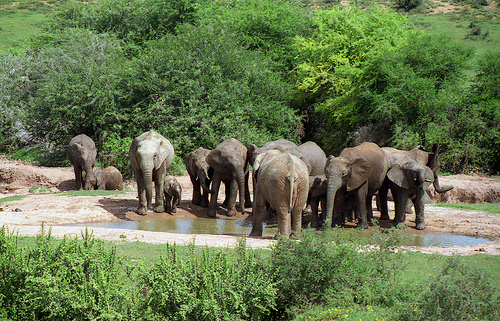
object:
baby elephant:
[162, 174, 182, 214]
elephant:
[66, 134, 97, 192]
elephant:
[185, 146, 216, 208]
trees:
[0, 32, 126, 165]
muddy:
[116, 201, 454, 235]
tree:
[292, 5, 420, 125]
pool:
[49, 214, 498, 249]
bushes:
[408, 254, 499, 319]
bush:
[0, 224, 79, 319]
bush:
[22, 226, 150, 319]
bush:
[139, 234, 198, 319]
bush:
[206, 233, 279, 319]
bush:
[266, 222, 356, 319]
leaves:
[360, 43, 372, 51]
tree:
[335, 36, 479, 150]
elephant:
[246, 148, 312, 243]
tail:
[286, 174, 298, 209]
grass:
[0, 235, 499, 294]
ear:
[343, 150, 374, 192]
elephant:
[128, 127, 175, 217]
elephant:
[205, 137, 253, 219]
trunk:
[323, 180, 341, 230]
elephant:
[321, 140, 391, 230]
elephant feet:
[136, 206, 148, 216]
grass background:
[0, 0, 499, 178]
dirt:
[0, 156, 499, 256]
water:
[52, 217, 497, 248]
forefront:
[0, 209, 500, 321]